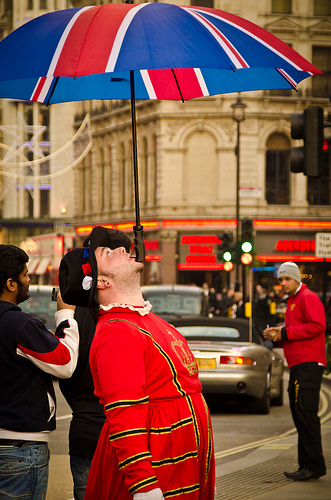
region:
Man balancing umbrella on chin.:
[3, 10, 296, 498]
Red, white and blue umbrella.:
[4, 1, 324, 115]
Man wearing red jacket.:
[278, 288, 329, 371]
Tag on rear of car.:
[196, 355, 216, 373]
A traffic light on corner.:
[221, 233, 262, 285]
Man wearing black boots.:
[282, 465, 328, 487]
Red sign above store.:
[168, 226, 223, 274]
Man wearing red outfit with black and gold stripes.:
[90, 307, 231, 496]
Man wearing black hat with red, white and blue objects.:
[57, 242, 100, 311]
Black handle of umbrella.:
[122, 72, 149, 263]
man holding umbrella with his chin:
[1, 0, 323, 296]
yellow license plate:
[189, 357, 222, 373]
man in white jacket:
[268, 261, 329, 371]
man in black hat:
[52, 226, 158, 321]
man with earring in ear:
[97, 274, 118, 297]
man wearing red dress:
[65, 225, 248, 481]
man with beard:
[0, 247, 34, 310]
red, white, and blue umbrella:
[0, 7, 323, 114]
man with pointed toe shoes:
[276, 464, 329, 483]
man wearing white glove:
[121, 486, 171, 498]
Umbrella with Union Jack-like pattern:
[3, 4, 326, 105]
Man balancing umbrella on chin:
[2, 1, 324, 275]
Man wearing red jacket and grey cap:
[263, 261, 326, 365]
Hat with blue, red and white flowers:
[56, 224, 104, 324]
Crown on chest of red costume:
[165, 327, 198, 381]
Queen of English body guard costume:
[83, 303, 214, 497]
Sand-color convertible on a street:
[194, 316, 283, 412]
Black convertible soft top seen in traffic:
[186, 317, 263, 344]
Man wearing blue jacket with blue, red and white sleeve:
[0, 243, 78, 439]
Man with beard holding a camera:
[0, 243, 75, 379]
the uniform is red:
[88, 320, 210, 445]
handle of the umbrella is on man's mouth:
[75, 196, 199, 310]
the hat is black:
[52, 243, 103, 314]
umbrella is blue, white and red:
[38, 9, 266, 113]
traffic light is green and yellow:
[236, 239, 258, 273]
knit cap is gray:
[271, 259, 305, 290]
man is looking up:
[57, 234, 153, 329]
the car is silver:
[182, 315, 286, 391]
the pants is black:
[283, 371, 323, 474]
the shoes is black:
[283, 460, 328, 475]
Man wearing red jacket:
[251, 257, 329, 483]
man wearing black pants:
[260, 259, 329, 483]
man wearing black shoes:
[260, 257, 329, 481]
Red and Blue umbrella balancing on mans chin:
[2, 0, 324, 497]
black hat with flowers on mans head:
[51, 225, 116, 324]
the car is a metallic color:
[157, 312, 287, 416]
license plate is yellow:
[193, 354, 219, 371]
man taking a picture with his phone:
[0, 230, 80, 494]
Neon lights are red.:
[73, 215, 328, 276]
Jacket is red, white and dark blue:
[0, 299, 82, 439]